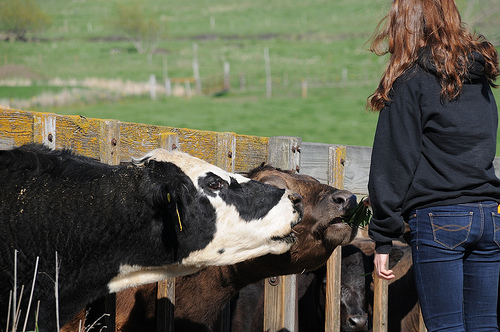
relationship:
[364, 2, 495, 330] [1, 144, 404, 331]
woman with cows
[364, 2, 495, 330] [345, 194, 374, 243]
woman holding plant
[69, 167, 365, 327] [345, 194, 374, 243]
cow eating plant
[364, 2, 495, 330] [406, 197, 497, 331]
woman wearing jeans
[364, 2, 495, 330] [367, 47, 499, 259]
woman wearing hoodie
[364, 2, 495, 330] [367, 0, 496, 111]
woman with hair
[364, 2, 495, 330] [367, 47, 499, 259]
woman in sweatshirt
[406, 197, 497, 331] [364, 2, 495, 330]
jeans on woman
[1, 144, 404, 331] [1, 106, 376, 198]
cows in fence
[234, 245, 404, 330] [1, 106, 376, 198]
cow in fence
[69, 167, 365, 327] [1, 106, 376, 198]
cow in fence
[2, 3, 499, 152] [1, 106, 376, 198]
grass by fence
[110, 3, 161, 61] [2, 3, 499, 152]
tree on grass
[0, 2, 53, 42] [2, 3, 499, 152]
tree on grass